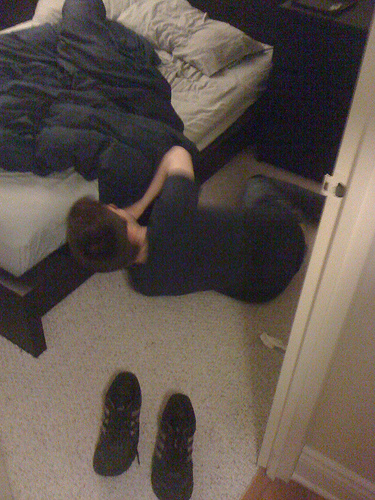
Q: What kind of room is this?
A: It is a bedroom.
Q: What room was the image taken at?
A: It was taken at the bedroom.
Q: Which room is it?
A: It is a bedroom.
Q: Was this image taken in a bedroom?
A: Yes, it was taken in a bedroom.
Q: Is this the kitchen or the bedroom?
A: It is the bedroom.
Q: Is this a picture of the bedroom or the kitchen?
A: It is showing the bedroom.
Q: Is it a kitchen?
A: No, it is a bedroom.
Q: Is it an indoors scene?
A: Yes, it is indoors.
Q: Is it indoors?
A: Yes, it is indoors.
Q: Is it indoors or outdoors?
A: It is indoors.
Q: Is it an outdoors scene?
A: No, it is indoors.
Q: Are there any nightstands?
A: Yes, there is a nightstand.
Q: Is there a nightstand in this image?
A: Yes, there is a nightstand.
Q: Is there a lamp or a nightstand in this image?
A: Yes, there is a nightstand.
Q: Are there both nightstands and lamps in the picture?
A: No, there is a nightstand but no lamps.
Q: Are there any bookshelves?
A: No, there are no bookshelves.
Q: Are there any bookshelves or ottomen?
A: No, there are no bookshelves or ottomen.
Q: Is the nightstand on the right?
A: Yes, the nightstand is on the right of the image.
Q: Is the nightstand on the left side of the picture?
A: No, the nightstand is on the right of the image.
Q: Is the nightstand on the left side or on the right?
A: The nightstand is on the right of the image.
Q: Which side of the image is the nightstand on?
A: The nightstand is on the right of the image.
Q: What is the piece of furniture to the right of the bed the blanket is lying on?
A: The piece of furniture is a nightstand.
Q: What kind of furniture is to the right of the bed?
A: The piece of furniture is a nightstand.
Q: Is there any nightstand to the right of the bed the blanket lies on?
A: Yes, there is a nightstand to the right of the bed.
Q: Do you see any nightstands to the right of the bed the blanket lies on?
A: Yes, there is a nightstand to the right of the bed.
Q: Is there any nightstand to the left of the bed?
A: No, the nightstand is to the right of the bed.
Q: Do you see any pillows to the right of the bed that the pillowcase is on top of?
A: No, there is a nightstand to the right of the bed.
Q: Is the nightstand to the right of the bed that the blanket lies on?
A: Yes, the nightstand is to the right of the bed.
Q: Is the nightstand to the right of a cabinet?
A: No, the nightstand is to the right of the bed.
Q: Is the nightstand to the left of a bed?
A: No, the nightstand is to the right of a bed.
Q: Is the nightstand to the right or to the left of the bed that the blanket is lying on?
A: The nightstand is to the right of the bed.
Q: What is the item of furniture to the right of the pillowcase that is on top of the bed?
A: The piece of furniture is a nightstand.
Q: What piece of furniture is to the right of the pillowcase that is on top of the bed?
A: The piece of furniture is a nightstand.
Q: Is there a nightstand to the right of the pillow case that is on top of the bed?
A: Yes, there is a nightstand to the right of the pillowcase.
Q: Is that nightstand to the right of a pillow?
A: No, the nightstand is to the right of the pillowcase.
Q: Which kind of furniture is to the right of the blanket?
A: The piece of furniture is a nightstand.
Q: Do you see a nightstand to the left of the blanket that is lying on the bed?
A: No, the nightstand is to the right of the blanket.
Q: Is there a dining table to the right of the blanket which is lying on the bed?
A: No, there is a nightstand to the right of the blanket.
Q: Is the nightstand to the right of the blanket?
A: Yes, the nightstand is to the right of the blanket.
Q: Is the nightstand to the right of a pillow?
A: No, the nightstand is to the right of the blanket.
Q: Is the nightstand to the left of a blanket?
A: No, the nightstand is to the right of a blanket.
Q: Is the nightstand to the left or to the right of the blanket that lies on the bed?
A: The nightstand is to the right of the blanket.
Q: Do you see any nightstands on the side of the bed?
A: Yes, there is a nightstand on the side of the bed.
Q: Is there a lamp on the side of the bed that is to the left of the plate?
A: No, there is a nightstand on the side of the bed.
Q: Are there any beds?
A: Yes, there is a bed.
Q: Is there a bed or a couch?
A: Yes, there is a bed.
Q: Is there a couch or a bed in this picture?
A: Yes, there is a bed.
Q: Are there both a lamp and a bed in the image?
A: No, there is a bed but no lamps.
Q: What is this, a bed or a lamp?
A: This is a bed.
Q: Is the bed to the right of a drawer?
A: No, the bed is to the left of a drawer.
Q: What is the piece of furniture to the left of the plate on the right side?
A: The piece of furniture is a bed.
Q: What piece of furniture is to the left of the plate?
A: The piece of furniture is a bed.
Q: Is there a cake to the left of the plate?
A: No, there is a bed to the left of the plate.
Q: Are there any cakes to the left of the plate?
A: No, there is a bed to the left of the plate.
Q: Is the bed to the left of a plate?
A: Yes, the bed is to the left of a plate.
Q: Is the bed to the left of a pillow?
A: No, the bed is to the left of a plate.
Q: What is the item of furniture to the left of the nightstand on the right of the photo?
A: The piece of furniture is a bed.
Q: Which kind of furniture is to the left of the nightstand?
A: The piece of furniture is a bed.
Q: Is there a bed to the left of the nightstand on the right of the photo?
A: Yes, there is a bed to the left of the nightstand.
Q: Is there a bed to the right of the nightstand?
A: No, the bed is to the left of the nightstand.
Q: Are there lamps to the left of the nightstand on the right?
A: No, there is a bed to the left of the nightstand.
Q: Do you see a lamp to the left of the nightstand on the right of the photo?
A: No, there is a bed to the left of the nightstand.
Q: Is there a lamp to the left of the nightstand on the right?
A: No, there is a bed to the left of the nightstand.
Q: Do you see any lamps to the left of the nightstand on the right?
A: No, there is a bed to the left of the nightstand.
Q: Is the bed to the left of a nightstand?
A: Yes, the bed is to the left of a nightstand.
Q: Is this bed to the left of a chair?
A: No, the bed is to the left of a nightstand.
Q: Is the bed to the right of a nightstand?
A: No, the bed is to the left of a nightstand.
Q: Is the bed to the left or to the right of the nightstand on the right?
A: The bed is to the left of the nightstand.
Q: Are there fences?
A: No, there are no fences.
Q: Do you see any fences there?
A: No, there are no fences.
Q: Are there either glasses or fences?
A: No, there are no fences or glasses.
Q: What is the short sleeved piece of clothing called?
A: The clothing item is a shirt.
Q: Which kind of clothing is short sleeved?
A: The clothing is a shirt.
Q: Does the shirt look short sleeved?
A: Yes, the shirt is short sleeved.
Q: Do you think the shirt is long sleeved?
A: No, the shirt is short sleeved.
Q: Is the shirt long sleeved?
A: No, the shirt is short sleeved.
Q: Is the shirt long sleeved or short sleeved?
A: The shirt is short sleeved.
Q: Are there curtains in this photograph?
A: No, there are no curtains.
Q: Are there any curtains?
A: No, there are no curtains.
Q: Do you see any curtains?
A: No, there are no curtains.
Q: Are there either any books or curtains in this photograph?
A: No, there are no curtains or books.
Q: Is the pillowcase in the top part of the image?
A: Yes, the pillowcase is in the top of the image.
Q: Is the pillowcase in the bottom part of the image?
A: No, the pillowcase is in the top of the image.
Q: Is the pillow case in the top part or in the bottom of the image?
A: The pillow case is in the top of the image.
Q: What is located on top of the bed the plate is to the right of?
A: The pillowcase is on top of the bed.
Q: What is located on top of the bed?
A: The pillowcase is on top of the bed.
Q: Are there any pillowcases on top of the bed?
A: Yes, there is a pillowcase on top of the bed.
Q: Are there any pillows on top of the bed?
A: No, there is a pillowcase on top of the bed.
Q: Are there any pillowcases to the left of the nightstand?
A: Yes, there is a pillowcase to the left of the nightstand.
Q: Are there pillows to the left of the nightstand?
A: No, there is a pillowcase to the left of the nightstand.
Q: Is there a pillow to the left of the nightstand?
A: No, there is a pillowcase to the left of the nightstand.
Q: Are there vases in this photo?
A: No, there are no vases.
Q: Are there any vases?
A: No, there are no vases.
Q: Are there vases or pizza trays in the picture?
A: No, there are no vases or pizza trays.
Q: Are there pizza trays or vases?
A: No, there are no vases or pizza trays.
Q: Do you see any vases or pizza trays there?
A: No, there are no vases or pizza trays.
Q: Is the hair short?
A: Yes, the hair is short.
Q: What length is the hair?
A: The hair is short.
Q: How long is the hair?
A: The hair is short.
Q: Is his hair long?
A: No, the hair is short.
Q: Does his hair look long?
A: No, the hair is short.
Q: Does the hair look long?
A: No, the hair is short.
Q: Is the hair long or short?
A: The hair is short.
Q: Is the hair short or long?
A: The hair is short.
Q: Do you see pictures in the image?
A: No, there are no pictures.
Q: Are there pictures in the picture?
A: No, there are no pictures.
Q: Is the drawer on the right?
A: Yes, the drawer is on the right of the image.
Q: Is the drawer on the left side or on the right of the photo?
A: The drawer is on the right of the image.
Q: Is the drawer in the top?
A: Yes, the drawer is in the top of the image.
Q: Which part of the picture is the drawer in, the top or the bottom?
A: The drawer is in the top of the image.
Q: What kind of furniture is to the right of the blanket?
A: The piece of furniture is a drawer.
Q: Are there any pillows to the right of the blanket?
A: No, there is a drawer to the right of the blanket.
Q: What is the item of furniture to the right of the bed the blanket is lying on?
A: The piece of furniture is a drawer.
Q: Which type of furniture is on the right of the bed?
A: The piece of furniture is a drawer.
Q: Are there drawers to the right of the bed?
A: Yes, there is a drawer to the right of the bed.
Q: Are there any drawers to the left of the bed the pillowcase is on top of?
A: No, the drawer is to the right of the bed.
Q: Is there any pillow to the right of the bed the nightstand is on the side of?
A: No, there is a drawer to the right of the bed.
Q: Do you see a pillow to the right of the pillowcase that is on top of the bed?
A: No, there is a drawer to the right of the pillowcase.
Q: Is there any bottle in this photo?
A: No, there are no bottles.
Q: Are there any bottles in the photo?
A: No, there are no bottles.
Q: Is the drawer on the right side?
A: Yes, the drawer is on the right of the image.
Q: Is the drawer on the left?
A: No, the drawer is on the right of the image.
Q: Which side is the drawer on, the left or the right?
A: The drawer is on the right of the image.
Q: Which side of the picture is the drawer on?
A: The drawer is on the right of the image.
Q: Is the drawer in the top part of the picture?
A: Yes, the drawer is in the top of the image.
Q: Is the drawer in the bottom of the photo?
A: No, the drawer is in the top of the image.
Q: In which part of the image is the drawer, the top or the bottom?
A: The drawer is in the top of the image.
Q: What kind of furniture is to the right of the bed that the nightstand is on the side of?
A: The piece of furniture is a drawer.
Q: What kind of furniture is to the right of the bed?
A: The piece of furniture is a drawer.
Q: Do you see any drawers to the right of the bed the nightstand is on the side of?
A: Yes, there is a drawer to the right of the bed.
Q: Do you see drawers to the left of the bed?
A: No, the drawer is to the right of the bed.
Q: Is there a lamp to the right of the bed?
A: No, there is a drawer to the right of the bed.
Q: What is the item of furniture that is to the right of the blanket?
A: The piece of furniture is a drawer.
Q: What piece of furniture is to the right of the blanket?
A: The piece of furniture is a drawer.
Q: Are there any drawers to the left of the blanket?
A: No, the drawer is to the right of the blanket.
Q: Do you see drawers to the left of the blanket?
A: No, the drawer is to the right of the blanket.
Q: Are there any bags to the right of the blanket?
A: No, there is a drawer to the right of the blanket.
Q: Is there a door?
A: Yes, there is a door.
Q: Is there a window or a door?
A: Yes, there is a door.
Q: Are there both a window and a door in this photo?
A: No, there is a door but no windows.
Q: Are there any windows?
A: No, there are no windows.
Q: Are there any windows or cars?
A: No, there are no windows or cars.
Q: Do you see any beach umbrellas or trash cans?
A: No, there are no trash cans or beach umbrellas.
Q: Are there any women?
A: No, there are no women.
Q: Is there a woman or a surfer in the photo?
A: No, there are no women or surfers.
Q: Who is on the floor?
A: The boy is on the floor.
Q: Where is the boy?
A: The boy is on the floor.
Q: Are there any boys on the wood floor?
A: Yes, there is a boy on the floor.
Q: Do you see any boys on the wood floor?
A: Yes, there is a boy on the floor.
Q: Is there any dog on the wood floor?
A: No, there is a boy on the floor.